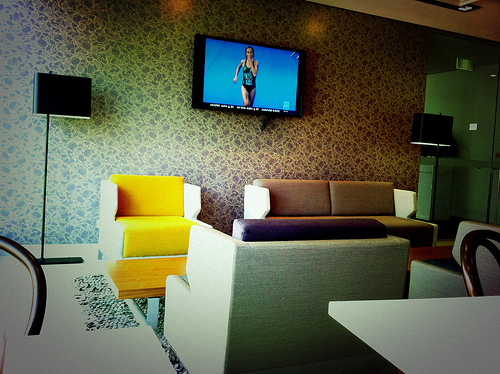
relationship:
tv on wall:
[193, 33, 303, 119] [8, 4, 500, 204]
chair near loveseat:
[97, 171, 205, 255] [240, 178, 437, 245]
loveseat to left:
[240, 178, 437, 245] [235, 5, 497, 371]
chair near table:
[97, 171, 205, 255] [107, 257, 165, 296]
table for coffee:
[107, 257, 165, 296] [105, 252, 213, 301]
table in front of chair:
[107, 257, 165, 296] [97, 171, 205, 255]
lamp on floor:
[33, 72, 97, 273] [14, 252, 182, 373]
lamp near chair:
[33, 72, 97, 273] [97, 171, 205, 255]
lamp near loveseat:
[33, 72, 97, 273] [240, 178, 437, 245]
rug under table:
[70, 273, 118, 328] [107, 257, 165, 296]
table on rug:
[107, 257, 165, 296] [70, 273, 118, 328]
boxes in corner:
[418, 158, 499, 236] [423, 33, 499, 239]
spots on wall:
[96, 35, 181, 154] [8, 4, 500, 204]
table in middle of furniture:
[234, 207, 376, 299] [89, 164, 437, 299]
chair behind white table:
[0, 232, 51, 336] [0, 311, 190, 370]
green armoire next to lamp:
[414, 66, 499, 233] [33, 72, 97, 268]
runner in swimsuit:
[234, 47, 261, 107] [235, 56, 259, 96]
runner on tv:
[234, 47, 261, 107] [184, 23, 321, 125]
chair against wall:
[0, 218, 61, 339] [3, 0, 453, 252]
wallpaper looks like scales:
[3, 0, 415, 260] [0, 1, 414, 181]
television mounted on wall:
[190, 30, 318, 127] [3, 0, 453, 252]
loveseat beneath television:
[233, 167, 451, 262] [185, 21, 314, 128]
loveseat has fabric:
[233, 167, 451, 262] [269, 180, 413, 237]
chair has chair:
[88, 167, 218, 255] [171, 214, 429, 366]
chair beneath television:
[88, 167, 218, 255] [190, 32, 308, 125]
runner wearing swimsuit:
[234, 47, 261, 107] [231, 57, 266, 98]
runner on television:
[234, 47, 261, 107] [183, 31, 313, 122]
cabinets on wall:
[375, 70, 490, 191] [35, 70, 490, 191]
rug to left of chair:
[64, 273, 118, 327] [64, 130, 245, 327]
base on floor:
[31, 239, 115, 269] [31, 239, 115, 269]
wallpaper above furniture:
[108, 71, 236, 159] [108, 71, 473, 338]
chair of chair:
[97, 171, 205, 255] [96, 183, 203, 247]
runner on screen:
[195, 47, 286, 124] [169, 20, 329, 112]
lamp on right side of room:
[399, 104, 491, 171] [4, 7, 492, 171]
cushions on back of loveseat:
[266, 183, 391, 225] [240, 178, 437, 245]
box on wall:
[26, 70, 121, 182] [26, 70, 121, 182]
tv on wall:
[193, 33, 303, 119] [178, 24, 369, 115]